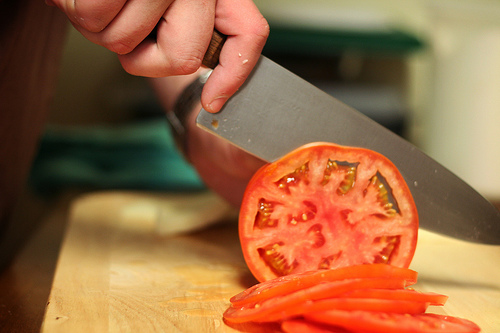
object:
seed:
[374, 180, 387, 192]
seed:
[297, 209, 310, 223]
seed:
[285, 215, 300, 226]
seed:
[260, 210, 276, 218]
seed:
[261, 247, 277, 257]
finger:
[199, 0, 273, 114]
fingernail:
[208, 97, 226, 113]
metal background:
[249, 11, 420, 135]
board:
[7, 188, 500, 332]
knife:
[127, 2, 499, 244]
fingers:
[114, 0, 216, 79]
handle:
[146, 14, 227, 70]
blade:
[195, 55, 499, 247]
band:
[165, 69, 214, 165]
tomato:
[223, 141, 481, 332]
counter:
[0, 185, 497, 333]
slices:
[228, 264, 416, 305]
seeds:
[376, 250, 390, 264]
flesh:
[349, 149, 409, 267]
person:
[0, 0, 271, 261]